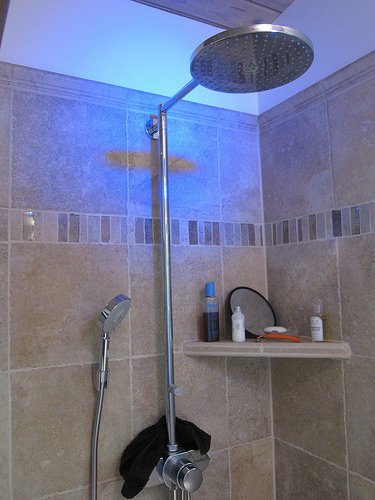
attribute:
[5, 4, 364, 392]
shower — silver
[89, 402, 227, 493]
washcloth — black, hanging, used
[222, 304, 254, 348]
soap — liquid, white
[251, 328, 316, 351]
razor — orange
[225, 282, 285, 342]
mirror — round, black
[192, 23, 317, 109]
head — metal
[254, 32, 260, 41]
holes — tiny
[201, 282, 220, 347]
bottle — plastic, full, clear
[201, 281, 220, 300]
top — blue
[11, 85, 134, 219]
tile — granite, brown, shower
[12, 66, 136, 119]
tile — oblong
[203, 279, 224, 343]
shampoo — black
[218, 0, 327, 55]
light — on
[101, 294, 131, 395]
shower head — silver, round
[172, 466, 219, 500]
button — round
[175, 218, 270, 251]
tiles — rectangle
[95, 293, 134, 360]
shower head — small, movable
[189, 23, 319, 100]
shower head — large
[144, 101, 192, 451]
piping — long, silver